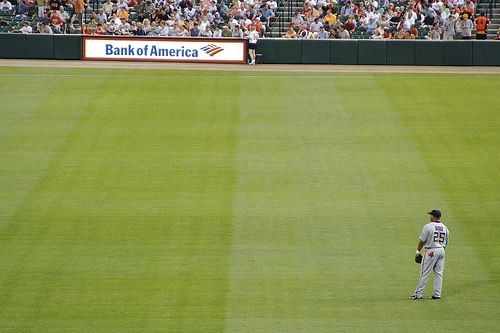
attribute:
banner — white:
[89, 31, 251, 66]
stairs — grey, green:
[262, 0, 305, 38]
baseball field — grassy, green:
[1, 73, 496, 331]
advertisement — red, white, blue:
[91, 23, 265, 75]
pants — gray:
[401, 244, 450, 306]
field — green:
[9, 48, 416, 330]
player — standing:
[410, 206, 451, 300]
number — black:
[431, 230, 446, 245]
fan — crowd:
[473, 10, 490, 37]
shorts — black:
[246, 41, 258, 51]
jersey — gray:
[414, 218, 450, 249]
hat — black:
[427, 207, 444, 221]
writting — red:
[434, 224, 447, 245]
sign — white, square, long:
[78, 32, 251, 67]